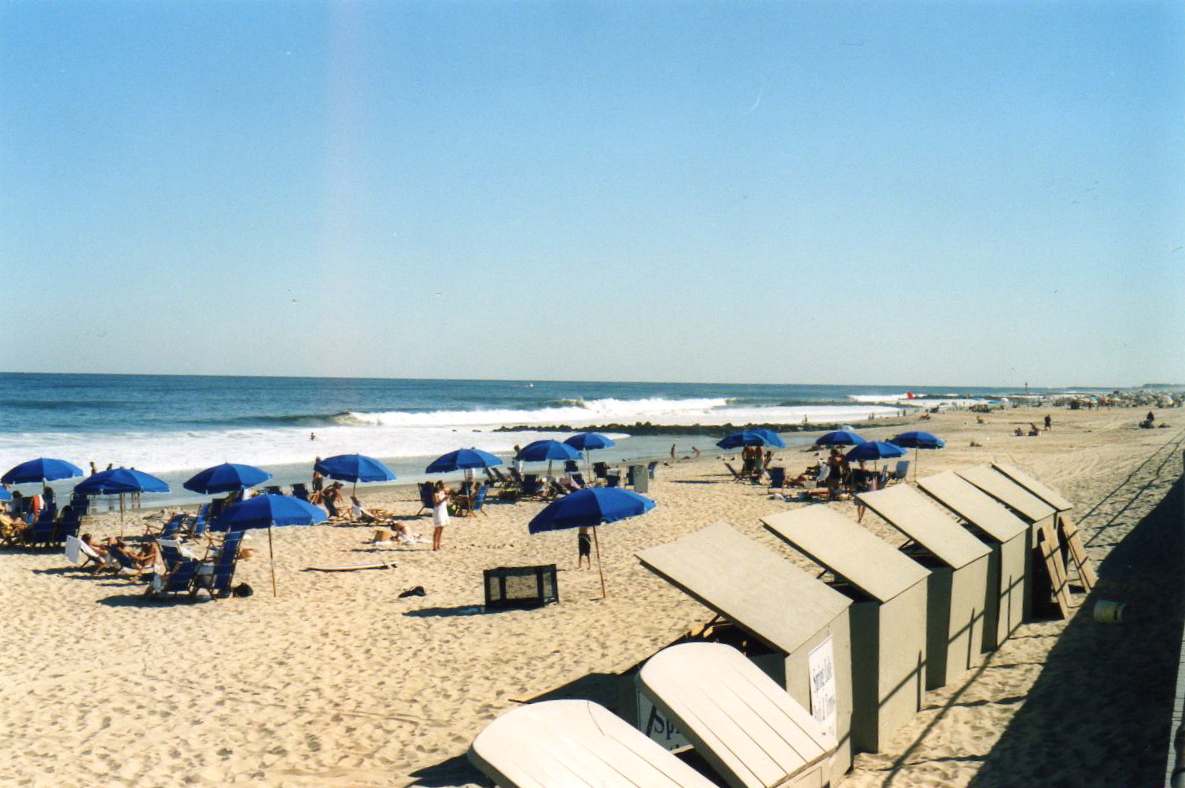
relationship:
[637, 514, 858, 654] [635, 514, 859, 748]
lid on dumpster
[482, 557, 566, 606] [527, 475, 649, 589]
crib under umbrella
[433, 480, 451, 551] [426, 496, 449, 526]
person wearing dress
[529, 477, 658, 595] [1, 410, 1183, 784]
umbrella stuck into sand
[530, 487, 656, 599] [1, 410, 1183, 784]
umbrella stuck into sand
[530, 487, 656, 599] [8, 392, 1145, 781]
umbrella on ground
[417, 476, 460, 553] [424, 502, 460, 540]
person wearing dress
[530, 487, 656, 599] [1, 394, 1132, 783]
umbrella on beach